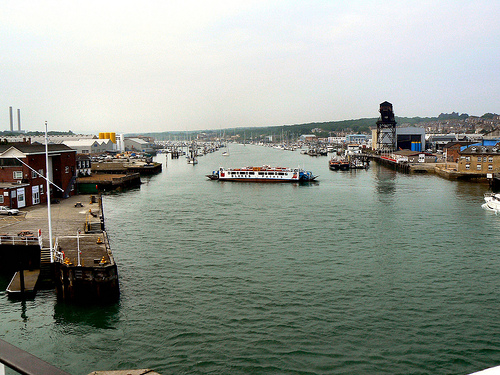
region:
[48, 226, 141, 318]
A short pier.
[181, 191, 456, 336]
Wavy greenish blue water.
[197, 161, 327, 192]
A ferry crossing a body of water.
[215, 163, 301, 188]
Many windows on a white ferry.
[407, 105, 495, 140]
A small hill.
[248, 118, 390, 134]
Green trees on a small hillside.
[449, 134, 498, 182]
A brown building next to a body of water.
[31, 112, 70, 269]
A tall white pole.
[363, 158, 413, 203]
Shadow of a building reflected in the water.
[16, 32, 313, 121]
Gray sky.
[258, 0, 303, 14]
a light blue sky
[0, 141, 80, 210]
a brown building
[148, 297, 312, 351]
green water with waves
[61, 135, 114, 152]
white buildings in background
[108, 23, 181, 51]
white clouds in sky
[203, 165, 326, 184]
boat in middle of water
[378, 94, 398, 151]
white and brown water tower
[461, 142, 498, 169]
small brown building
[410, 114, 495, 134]
houses in the background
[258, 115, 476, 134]
hill or mountains in background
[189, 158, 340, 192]
boat is blue white and red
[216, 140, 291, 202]
boat is blue white and red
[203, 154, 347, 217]
boat is blue white and red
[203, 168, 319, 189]
boat is blue white and red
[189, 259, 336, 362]
calm green waters in the bay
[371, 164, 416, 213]
shadow in the water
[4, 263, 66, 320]
small pier over the water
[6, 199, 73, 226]
small white car on shore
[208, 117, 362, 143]
wide mountain range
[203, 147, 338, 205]
large red and white cruise line boat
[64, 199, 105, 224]
white spot on ground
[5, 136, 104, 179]
black slanted house roof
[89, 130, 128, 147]
large round yellow buildings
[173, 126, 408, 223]
boats in the harbor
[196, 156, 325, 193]
A long, mostly white boat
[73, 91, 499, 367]
A large patch of water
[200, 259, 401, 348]
Ripples on the water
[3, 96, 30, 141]
Smoke stacks in the distance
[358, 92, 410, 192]
A tower by the water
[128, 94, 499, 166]
A small hill on the horizon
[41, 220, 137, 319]
A wooden boat dock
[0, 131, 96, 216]
A rusty red building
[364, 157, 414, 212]
The reflection of a tower in the water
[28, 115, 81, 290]
A tall white pole